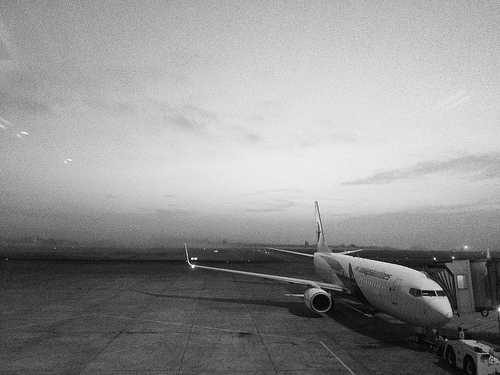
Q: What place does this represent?
A: It represents the road.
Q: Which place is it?
A: It is a road.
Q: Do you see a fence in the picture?
A: No, there are no fences.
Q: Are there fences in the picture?
A: No, there are no fences.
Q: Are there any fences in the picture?
A: No, there are no fences.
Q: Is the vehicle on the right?
A: Yes, the vehicle is on the right of the image.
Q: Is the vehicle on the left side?
A: No, the vehicle is on the right of the image.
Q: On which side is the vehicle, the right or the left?
A: The vehicle is on the right of the image.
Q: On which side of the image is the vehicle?
A: The vehicle is on the right of the image.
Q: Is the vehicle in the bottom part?
A: Yes, the vehicle is in the bottom of the image.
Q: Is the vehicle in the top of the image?
A: No, the vehicle is in the bottom of the image.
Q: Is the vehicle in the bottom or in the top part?
A: The vehicle is in the bottom of the image.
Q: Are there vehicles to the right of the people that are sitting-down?
A: Yes, there is a vehicle to the right of the people.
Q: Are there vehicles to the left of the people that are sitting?
A: No, the vehicle is to the right of the people.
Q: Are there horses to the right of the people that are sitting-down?
A: No, there is a vehicle to the right of the people.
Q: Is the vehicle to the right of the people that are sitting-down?
A: Yes, the vehicle is to the right of the people.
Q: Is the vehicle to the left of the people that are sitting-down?
A: No, the vehicle is to the right of the people.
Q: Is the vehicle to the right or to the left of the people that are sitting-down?
A: The vehicle is to the right of the people.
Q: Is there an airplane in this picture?
A: Yes, there is an airplane.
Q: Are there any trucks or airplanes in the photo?
A: Yes, there is an airplane.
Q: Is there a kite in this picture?
A: No, there are no kites.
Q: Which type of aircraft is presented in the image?
A: The aircraft is an airplane.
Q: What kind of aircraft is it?
A: The aircraft is an airplane.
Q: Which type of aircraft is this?
A: This is an airplane.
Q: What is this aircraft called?
A: This is an airplane.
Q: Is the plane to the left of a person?
A: Yes, the plane is to the left of a person.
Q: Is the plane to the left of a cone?
A: No, the plane is to the left of a person.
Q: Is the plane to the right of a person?
A: No, the plane is to the left of a person.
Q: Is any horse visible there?
A: No, there are no horses.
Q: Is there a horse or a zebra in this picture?
A: No, there are no horses or zebras.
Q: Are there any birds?
A: No, there are no birds.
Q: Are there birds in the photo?
A: No, there are no birds.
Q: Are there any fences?
A: No, there are no fences.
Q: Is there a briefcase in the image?
A: No, there are no briefcases.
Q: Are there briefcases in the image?
A: No, there are no briefcases.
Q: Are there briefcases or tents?
A: No, there are no briefcases or tents.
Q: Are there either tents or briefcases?
A: No, there are no briefcases or tents.